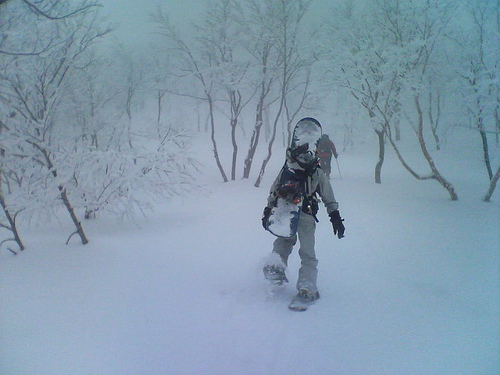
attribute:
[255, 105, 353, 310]
person — walking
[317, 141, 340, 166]
jacket — red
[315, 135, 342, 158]
jacket — red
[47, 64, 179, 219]
branches — snowy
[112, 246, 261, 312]
snow — white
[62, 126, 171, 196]
branches — tree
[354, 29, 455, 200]
branches — tree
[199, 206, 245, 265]
snow — white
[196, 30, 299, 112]
branches — tree